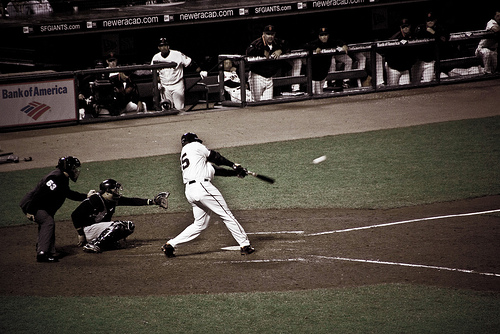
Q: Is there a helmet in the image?
A: Yes, there is a helmet.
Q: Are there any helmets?
A: Yes, there is a helmet.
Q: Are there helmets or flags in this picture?
A: Yes, there is a helmet.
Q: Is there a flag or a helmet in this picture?
A: Yes, there is a helmet.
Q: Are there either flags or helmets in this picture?
A: Yes, there is a helmet.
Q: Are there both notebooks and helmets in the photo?
A: No, there is a helmet but no notebooks.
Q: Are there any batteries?
A: No, there are no batteries.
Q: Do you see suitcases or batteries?
A: No, there are no batteries or suitcases.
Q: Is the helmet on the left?
A: Yes, the helmet is on the left of the image.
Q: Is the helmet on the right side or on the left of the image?
A: The helmet is on the left of the image.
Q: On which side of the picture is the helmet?
A: The helmet is on the left of the image.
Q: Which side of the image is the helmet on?
A: The helmet is on the left of the image.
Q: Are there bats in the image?
A: Yes, there is a bat.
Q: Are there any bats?
A: Yes, there is a bat.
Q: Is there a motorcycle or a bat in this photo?
A: Yes, there is a bat.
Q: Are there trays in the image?
A: No, there are no trays.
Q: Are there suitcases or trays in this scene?
A: No, there are no trays or suitcases.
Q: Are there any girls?
A: No, there are no girls.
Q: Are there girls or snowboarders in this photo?
A: No, there are no girls or snowboarders.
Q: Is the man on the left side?
A: Yes, the man is on the left of the image.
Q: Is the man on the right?
A: No, the man is on the left of the image.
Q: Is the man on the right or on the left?
A: The man is on the left of the image.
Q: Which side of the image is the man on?
A: The man is on the left of the image.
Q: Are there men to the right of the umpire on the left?
A: Yes, there is a man to the right of the umpire.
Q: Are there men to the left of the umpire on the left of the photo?
A: No, the man is to the right of the umpire.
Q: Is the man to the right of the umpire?
A: Yes, the man is to the right of the umpire.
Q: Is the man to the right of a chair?
A: No, the man is to the right of the umpire.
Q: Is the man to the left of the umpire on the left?
A: No, the man is to the right of the umpire.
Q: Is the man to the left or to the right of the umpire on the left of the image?
A: The man is to the right of the umpire.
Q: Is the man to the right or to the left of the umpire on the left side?
A: The man is to the right of the umpire.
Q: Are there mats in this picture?
A: No, there are no mats.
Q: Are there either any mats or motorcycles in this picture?
A: No, there are no mats or motorcycles.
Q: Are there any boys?
A: No, there are no boys.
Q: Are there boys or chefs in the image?
A: No, there are no boys or chefs.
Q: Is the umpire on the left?
A: Yes, the umpire is on the left of the image.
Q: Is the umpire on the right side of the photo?
A: No, the umpire is on the left of the image.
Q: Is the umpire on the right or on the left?
A: The umpire is on the left of the image.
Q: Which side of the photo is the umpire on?
A: The umpire is on the left of the image.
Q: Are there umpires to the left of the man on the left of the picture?
A: Yes, there is an umpire to the left of the man.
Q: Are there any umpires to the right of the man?
A: No, the umpire is to the left of the man.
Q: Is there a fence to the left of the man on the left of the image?
A: No, there is an umpire to the left of the man.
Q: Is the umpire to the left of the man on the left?
A: Yes, the umpire is to the left of the man.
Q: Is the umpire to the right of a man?
A: No, the umpire is to the left of a man.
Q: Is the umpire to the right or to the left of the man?
A: The umpire is to the left of the man.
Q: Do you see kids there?
A: No, there are no kids.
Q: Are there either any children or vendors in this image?
A: No, there are no children or vendors.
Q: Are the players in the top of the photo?
A: Yes, the players are in the top of the image.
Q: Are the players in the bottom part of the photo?
A: No, the players are in the top of the image.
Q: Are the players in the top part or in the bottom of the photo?
A: The players are in the top of the image.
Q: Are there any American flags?
A: No, there are no American flags.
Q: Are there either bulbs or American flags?
A: No, there are no American flags or bulbs.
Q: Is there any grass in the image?
A: Yes, there is grass.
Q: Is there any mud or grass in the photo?
A: Yes, there is grass.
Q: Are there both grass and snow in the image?
A: No, there is grass but no snow.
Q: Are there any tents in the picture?
A: No, there are no tents.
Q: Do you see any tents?
A: No, there are no tents.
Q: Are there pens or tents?
A: No, there are no tents or pens.